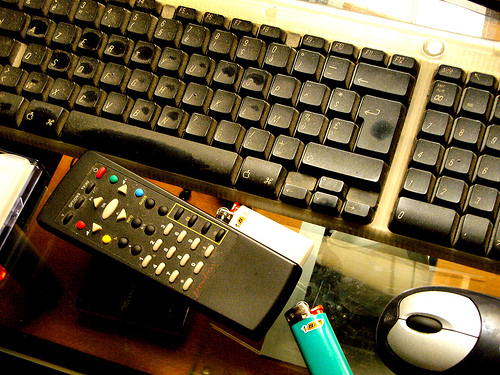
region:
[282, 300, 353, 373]
blue disposable lighter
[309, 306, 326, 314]
red button on lighter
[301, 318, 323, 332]
yellow logo on lighter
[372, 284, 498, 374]
black and gray two button mouse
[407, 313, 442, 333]
black scroll wheel on mouse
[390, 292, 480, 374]
the buttons on the mouse are light gray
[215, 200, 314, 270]
white disposable lighter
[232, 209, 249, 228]
orange logo on white lighter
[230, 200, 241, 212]
red plastic button on white lighter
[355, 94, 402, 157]
black enter key on keyboard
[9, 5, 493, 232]
computer keyboard on desk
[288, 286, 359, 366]
light green bic lighter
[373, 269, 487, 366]
gray and black wireless mouse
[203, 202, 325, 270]
small white bic lighter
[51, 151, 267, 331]
television remote control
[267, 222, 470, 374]
glass top work space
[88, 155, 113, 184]
red power button on remote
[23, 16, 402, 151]
worn and used keys on keyboard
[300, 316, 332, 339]
yellow bic label on lighter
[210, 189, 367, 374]
two bic lighters on table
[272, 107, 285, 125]
The M key on a keyboard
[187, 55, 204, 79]
The U key on a keyboard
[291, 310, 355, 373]
A teal colored BIC lighter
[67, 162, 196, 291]
A TV Remote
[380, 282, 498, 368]
A black and silver computer mouse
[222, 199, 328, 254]
A white colored BIC lighter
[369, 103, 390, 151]
The enter key on a keyboard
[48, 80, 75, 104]
The X key on a keyboard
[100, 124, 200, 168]
The spacebar on a keyboard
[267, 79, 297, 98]
The P key on a keyboard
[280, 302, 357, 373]
an aqua blue Bic lighter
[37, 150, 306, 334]
colorful buttons on a black control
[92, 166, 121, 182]
red and green buttons on a black control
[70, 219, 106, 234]
red and white buttons on a black control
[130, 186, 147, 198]
blue button on a black control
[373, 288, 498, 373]
silver and black computer mouse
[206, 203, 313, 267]
white BIC lighter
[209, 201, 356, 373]
two Bic lighters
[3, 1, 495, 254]
black keys on a keyboard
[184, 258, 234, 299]
red print on a black control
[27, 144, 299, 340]
A black remote.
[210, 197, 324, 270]
A white bic lighter.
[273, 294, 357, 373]
Part of a green lighter.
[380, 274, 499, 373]
S computer mouse.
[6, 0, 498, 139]
A keyboard for a computer.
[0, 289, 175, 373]
Stuff under the desk.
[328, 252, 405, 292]
The glass computer desk.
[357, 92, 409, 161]
The enter key on board.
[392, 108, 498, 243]
The number pad on keyboard.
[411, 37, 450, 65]
A circle button on keyboard.